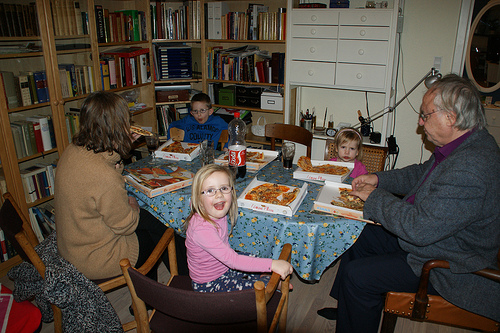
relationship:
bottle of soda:
[206, 102, 265, 189] [222, 143, 253, 181]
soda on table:
[222, 143, 253, 181] [126, 102, 419, 300]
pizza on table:
[301, 157, 352, 179] [129, 147, 374, 287]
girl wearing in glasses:
[178, 160, 299, 287] [199, 186, 231, 196]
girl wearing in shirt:
[178, 163, 297, 294] [181, 211, 275, 283]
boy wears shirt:
[169, 118, 235, 149] [167, 113, 232, 152]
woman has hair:
[53, 89, 188, 318] [70, 88, 137, 164]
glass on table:
[279, 140, 297, 167] [117, 142, 392, 259]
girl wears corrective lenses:
[178, 163, 297, 294] [198, 184, 233, 194]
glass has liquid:
[280, 140, 295, 170] [291, 101, 321, 167]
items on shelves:
[291, 104, 383, 144] [281, 7, 411, 152]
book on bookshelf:
[139, 52, 149, 82] [3, 2, 284, 114]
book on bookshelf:
[128, 56, 138, 86] [3, 2, 284, 114]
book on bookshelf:
[85, 62, 98, 93] [3, 2, 284, 114]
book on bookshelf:
[80, 64, 92, 92] [3, 2, 284, 114]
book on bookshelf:
[25, 112, 53, 154] [3, 2, 284, 114]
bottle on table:
[222, 110, 252, 180] [119, 150, 369, 283]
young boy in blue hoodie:
[167, 92, 234, 144] [168, 114, 230, 147]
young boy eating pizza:
[167, 92, 234, 144] [156, 134, 210, 159]